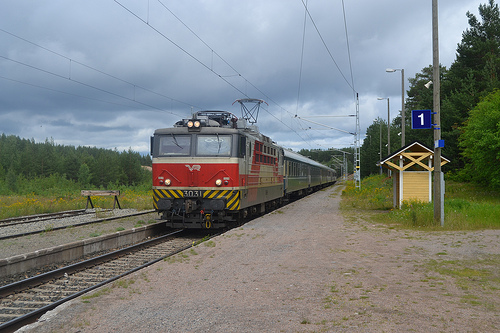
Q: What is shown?
A: A train.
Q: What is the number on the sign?
A: 1.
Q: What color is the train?
A: Red, grey, yellow, and black.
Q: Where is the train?
A: On the tracks.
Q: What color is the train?
A: Red.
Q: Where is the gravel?
A: Under the tracks.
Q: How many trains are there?
A: 1.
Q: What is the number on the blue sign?
A: 1.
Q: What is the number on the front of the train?
A: 3031.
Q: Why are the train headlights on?
A: To see.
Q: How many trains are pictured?
A: One.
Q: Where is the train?
A: On train tracks.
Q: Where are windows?
A: On the train.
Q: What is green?
A: Grass.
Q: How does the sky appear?
A: Cloudy.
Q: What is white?
A: Clouds.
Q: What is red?
A: Train.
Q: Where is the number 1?
A: On blue sign.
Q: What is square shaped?
A: Blue sign.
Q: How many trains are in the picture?
A: One.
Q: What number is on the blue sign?
A: The number one.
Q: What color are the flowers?
A: Yellow.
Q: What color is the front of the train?
A: Red.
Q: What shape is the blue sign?
A: Square.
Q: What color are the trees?
A: Green.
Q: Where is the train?
A: On the tracks.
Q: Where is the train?
A: On the tracks.